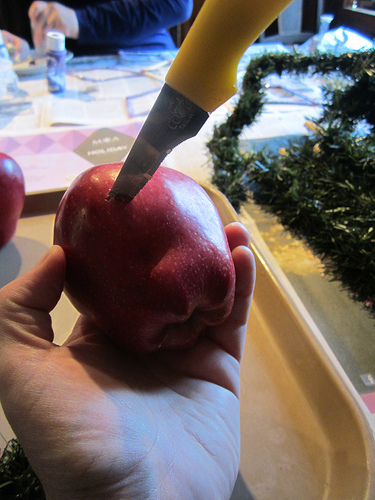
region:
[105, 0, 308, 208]
a knife stuck into an apple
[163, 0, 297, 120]
a yellow handle on the knife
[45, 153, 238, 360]
a red apple in the person's hand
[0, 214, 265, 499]
a person's hand holding an apple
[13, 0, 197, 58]
a person sitting at the table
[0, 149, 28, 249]
an apple on a food tray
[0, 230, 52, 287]
the shadow of the apple on the food tray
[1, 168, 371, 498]
a beige colored food tray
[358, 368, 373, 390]
a small Facebook logo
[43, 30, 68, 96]
a small bottle on the table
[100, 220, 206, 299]
An apple in the hand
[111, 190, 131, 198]
A knife in an apple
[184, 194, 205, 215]
Reflection of light on the apple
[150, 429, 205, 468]
Light reflection on the palm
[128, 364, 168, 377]
Apple casting shadow in the hand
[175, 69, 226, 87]
The handle of the knife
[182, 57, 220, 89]
Yellow handle of knife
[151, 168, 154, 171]
The blade of the knife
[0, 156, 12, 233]
An apple sticking out on the side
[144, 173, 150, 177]
An apple skin on the knife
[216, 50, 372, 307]
green needles on garland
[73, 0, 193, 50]
long sleeve of shirt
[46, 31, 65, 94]
tube with white cap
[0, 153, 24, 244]
edge of upright apple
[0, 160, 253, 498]
apple in person's hand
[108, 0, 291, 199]
knife with yellow handle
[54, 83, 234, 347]
knife blade in apple skin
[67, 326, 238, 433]
palm of open hand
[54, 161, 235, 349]
red skin on apple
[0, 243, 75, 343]
bent thumb on apple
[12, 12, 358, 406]
close-up of a red apple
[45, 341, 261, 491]
palm of a hand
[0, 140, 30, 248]
apple on a tray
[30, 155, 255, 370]
hand holding fruit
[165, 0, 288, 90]
plastic handle of knife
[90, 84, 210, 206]
blade of knife sticking in fruit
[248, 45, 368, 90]
coil of artificial grass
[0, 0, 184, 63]
person seated at a table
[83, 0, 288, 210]
knife cutting into an apple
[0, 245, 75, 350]
thumb pressed against fruit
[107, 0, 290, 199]
Knife stuck in an apple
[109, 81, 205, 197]
metal blade of the knife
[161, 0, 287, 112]
yellow handle of the knife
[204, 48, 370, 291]
green garland partially coiled up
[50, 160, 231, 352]
smooth red apple with tiny yellow spots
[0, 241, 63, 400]
thumb bent slightly inwards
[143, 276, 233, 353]
bumps on the bottom of the apple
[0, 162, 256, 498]
human hand holding an apple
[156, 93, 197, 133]
writing on the metal knife blade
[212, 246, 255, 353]
little finger touching apple